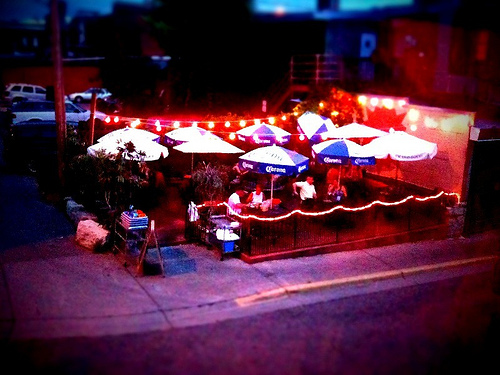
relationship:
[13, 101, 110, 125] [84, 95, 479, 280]
white truck behind outdoor cafe